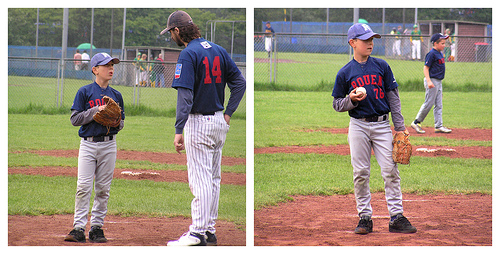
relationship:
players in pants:
[394, 26, 421, 60] [261, 36, 273, 56]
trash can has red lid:
[469, 37, 489, 62] [471, 40, 488, 49]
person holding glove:
[67, 52, 126, 242] [91, 92, 119, 125]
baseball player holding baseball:
[331, 21, 416, 233] [352, 85, 362, 100]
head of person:
[76, 48, 141, 98] [61, 50, 123, 246]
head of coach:
[157, 12, 197, 47] [157, 10, 248, 245]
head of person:
[87, 51, 122, 82] [67, 50, 126, 242]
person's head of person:
[427, 31, 449, 53] [410, 28, 456, 137]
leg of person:
[432, 78, 453, 134] [410, 28, 456, 137]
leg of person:
[411, 86, 442, 134] [411, 29, 451, 134]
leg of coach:
[180, 150, 217, 232] [157, 10, 248, 245]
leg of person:
[70, 136, 96, 230] [63, 31, 144, 249]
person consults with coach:
[67, 52, 126, 242] [152, 8, 247, 242]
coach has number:
[136, 14, 282, 211] [199, 50, 225, 87]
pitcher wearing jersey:
[326, 20, 417, 236] [334, 58, 396, 119]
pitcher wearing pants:
[344, 111, 406, 223] [326, 115, 440, 227]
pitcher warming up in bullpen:
[326, 20, 417, 236] [387, 19, 485, 64]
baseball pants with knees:
[75, 136, 115, 231] [74, 186, 111, 198]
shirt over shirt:
[168, 43, 237, 115] [170, 69, 247, 138]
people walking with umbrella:
[73, 50, 90, 71] [74, 40, 97, 53]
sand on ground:
[247, 181, 494, 251] [254, 43, 491, 243]